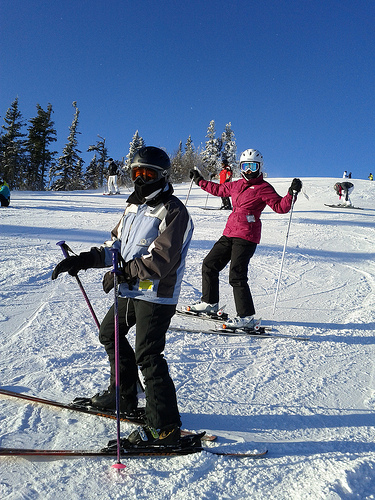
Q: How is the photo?
A: Clear.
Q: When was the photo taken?
A: Daytime.